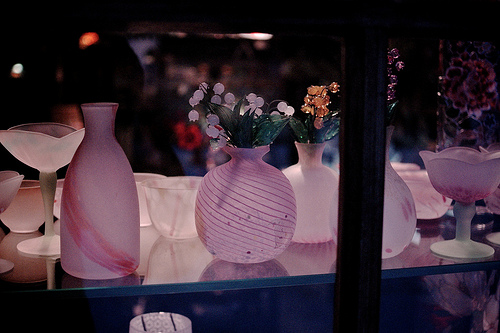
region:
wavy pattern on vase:
[183, 143, 308, 263]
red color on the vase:
[53, 194, 133, 272]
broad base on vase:
[428, 229, 495, 264]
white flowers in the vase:
[181, 77, 248, 122]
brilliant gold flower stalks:
[296, 76, 335, 119]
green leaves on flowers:
[228, 115, 290, 147]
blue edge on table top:
[138, 270, 219, 297]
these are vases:
[24, 14, 474, 304]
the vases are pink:
[71, 77, 323, 311]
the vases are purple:
[220, 164, 285, 255]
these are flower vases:
[190, 88, 320, 185]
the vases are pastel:
[54, 74, 301, 265]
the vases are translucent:
[68, 78, 289, 302]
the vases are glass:
[198, 83, 326, 158]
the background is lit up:
[135, 47, 262, 141]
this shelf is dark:
[64, 80, 498, 285]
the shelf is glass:
[125, 241, 323, 283]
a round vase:
[192, 154, 309, 261]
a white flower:
[191, 112, 235, 140]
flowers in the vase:
[187, 86, 263, 138]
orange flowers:
[309, 78, 334, 117]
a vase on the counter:
[296, 172, 333, 206]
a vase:
[66, 104, 141, 281]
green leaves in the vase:
[236, 113, 273, 137]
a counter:
[288, 250, 321, 277]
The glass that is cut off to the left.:
[0, 165, 25, 272]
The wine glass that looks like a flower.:
[2, 122, 74, 282]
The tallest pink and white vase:
[64, 90, 137, 285]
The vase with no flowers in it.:
[45, 80, 169, 280]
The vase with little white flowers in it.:
[181, 80, 296, 282]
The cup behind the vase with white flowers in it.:
[139, 168, 200, 240]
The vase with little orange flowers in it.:
[286, 77, 348, 239]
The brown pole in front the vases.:
[328, 60, 393, 318]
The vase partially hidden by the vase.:
[344, 53, 421, 250]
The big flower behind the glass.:
[442, 56, 496, 121]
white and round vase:
[175, 130, 293, 281]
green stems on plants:
[208, 98, 278, 180]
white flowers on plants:
[177, 68, 249, 170]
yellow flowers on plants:
[277, 58, 355, 190]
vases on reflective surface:
[75, 124, 336, 304]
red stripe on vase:
[61, 163, 123, 284]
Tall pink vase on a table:
[61, 98, 142, 280]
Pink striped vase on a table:
[192, 143, 299, 258]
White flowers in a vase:
[190, 86, 291, 137]